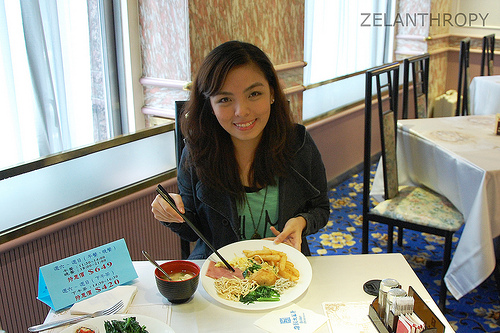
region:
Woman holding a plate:
[142, 33, 335, 268]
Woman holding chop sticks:
[150, 35, 336, 262]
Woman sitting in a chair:
[161, 38, 334, 262]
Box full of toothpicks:
[387, 294, 414, 329]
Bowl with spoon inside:
[138, 247, 201, 304]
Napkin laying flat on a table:
[252, 300, 328, 332]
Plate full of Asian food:
[200, 231, 308, 309]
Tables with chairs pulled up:
[358, 28, 498, 306]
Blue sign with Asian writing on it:
[27, 234, 142, 312]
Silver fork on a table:
[20, 299, 134, 331]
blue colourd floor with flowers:
[336, 188, 358, 241]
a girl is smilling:
[208, 74, 290, 142]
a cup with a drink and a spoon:
[141, 253, 201, 300]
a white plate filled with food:
[205, 240, 308, 309]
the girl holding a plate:
[205, 214, 318, 324]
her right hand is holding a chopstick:
[153, 178, 238, 282]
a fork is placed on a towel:
[36, 294, 124, 331]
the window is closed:
[5, 13, 108, 150]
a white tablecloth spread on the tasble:
[401, 125, 499, 294]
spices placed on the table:
[378, 275, 443, 330]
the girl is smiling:
[231, 118, 264, 133]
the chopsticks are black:
[186, 224, 214, 256]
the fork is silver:
[65, 297, 128, 319]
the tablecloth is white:
[464, 154, 491, 203]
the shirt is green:
[243, 195, 268, 220]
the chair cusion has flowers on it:
[406, 192, 438, 215]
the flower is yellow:
[325, 226, 357, 251]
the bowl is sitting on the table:
[168, 285, 193, 310]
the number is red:
[63, 262, 116, 281]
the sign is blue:
[63, 266, 116, 283]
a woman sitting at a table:
[153, 38, 332, 254]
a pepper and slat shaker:
[377, 275, 404, 322]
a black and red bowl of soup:
[153, 255, 202, 301]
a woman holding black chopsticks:
[150, 183, 234, 269]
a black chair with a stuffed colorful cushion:
[361, 62, 463, 312]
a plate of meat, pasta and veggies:
[201, 236, 313, 308]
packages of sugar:
[396, 310, 426, 332]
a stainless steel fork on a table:
[28, 300, 125, 331]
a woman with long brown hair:
[182, 40, 302, 207]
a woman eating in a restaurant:
[155, 39, 332, 311]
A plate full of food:
[207, 240, 312, 307]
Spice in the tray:
[376, 278, 406, 305]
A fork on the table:
[27, 302, 123, 332]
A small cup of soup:
[153, 260, 195, 296]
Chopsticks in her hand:
[154, 185, 238, 269]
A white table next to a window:
[46, 251, 458, 331]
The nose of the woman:
[234, 101, 248, 116]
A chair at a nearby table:
[359, 64, 466, 304]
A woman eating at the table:
[156, 44, 330, 257]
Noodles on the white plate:
[218, 276, 258, 299]